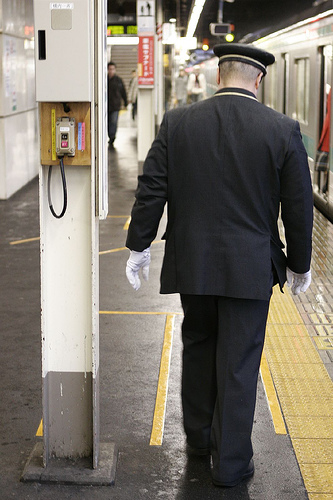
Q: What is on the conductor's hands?
A: Gloves.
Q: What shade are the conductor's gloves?
A: White.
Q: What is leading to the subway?
A: Stairs.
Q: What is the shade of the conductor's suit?
A: Black.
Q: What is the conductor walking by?
A: Telephone.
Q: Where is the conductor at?
A: Subway station.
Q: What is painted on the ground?
A: Lines.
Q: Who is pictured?
A: Train attendant.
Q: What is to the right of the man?
A: A train.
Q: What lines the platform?
A: Yellow border.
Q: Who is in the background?
A: People walking.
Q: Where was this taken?
A: A metro station.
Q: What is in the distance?
A: Stairs.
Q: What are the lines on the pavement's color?
A: Yellow.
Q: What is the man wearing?
A: Uniform.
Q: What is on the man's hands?
A: Gloves.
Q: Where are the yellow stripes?
A: Floor.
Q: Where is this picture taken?
A: Subway.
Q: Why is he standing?
A: To walk.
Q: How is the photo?
A: Clear.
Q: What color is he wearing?
A: Black.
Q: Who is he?
A: A man.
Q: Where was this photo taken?
A: Train station.